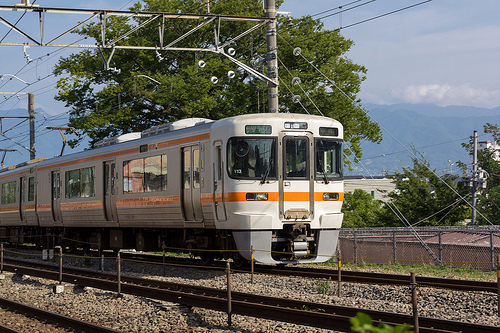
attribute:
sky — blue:
[418, 36, 471, 80]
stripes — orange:
[1, 130, 212, 180]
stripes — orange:
[4, 189, 344, 204]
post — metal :
[330, 249, 356, 310]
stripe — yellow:
[325, 256, 347, 268]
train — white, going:
[7, 110, 354, 270]